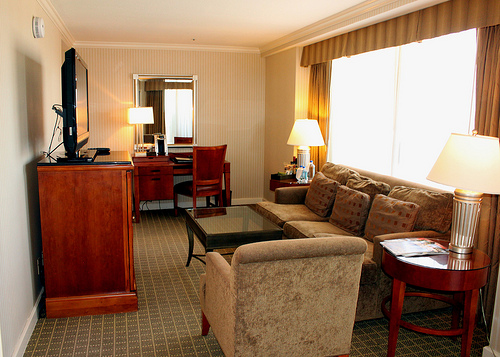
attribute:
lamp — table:
[281, 117, 326, 179]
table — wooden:
[267, 170, 323, 195]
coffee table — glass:
[182, 204, 284, 252]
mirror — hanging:
[131, 73, 197, 148]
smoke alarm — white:
[27, 7, 42, 36]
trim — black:
[183, 208, 269, 270]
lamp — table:
[428, 132, 499, 252]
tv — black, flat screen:
[57, 46, 99, 164]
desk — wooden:
[128, 132, 230, 217]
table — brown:
[379, 236, 496, 355]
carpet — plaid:
[25, 216, 490, 353]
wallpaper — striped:
[233, 52, 256, 186]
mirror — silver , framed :
[133, 72, 200, 150]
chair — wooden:
[176, 142, 227, 212]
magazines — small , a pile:
[340, 182, 450, 276]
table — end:
[328, 169, 490, 324]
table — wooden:
[92, 144, 235, 210]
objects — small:
[253, 148, 314, 198]